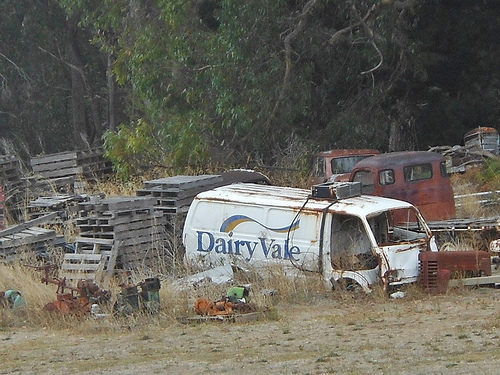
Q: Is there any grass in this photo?
A: Yes, there is grass.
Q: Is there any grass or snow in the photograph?
A: Yes, there is grass.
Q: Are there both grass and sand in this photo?
A: No, there is grass but no sand.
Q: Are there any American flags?
A: No, there are no American flags.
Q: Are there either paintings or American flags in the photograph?
A: No, there are no American flags or paintings.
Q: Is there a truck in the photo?
A: Yes, there is a truck.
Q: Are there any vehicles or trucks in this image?
A: Yes, there is a truck.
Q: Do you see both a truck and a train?
A: No, there is a truck but no trains.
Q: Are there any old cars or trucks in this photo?
A: Yes, there is an old truck.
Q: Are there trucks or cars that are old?
A: Yes, the truck is old.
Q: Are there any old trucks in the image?
A: Yes, there is an old truck.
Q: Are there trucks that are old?
A: Yes, there is a truck that is old.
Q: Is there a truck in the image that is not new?
A: Yes, there is a old truck.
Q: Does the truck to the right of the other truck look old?
A: Yes, the truck is old.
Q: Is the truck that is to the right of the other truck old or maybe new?
A: The truck is old.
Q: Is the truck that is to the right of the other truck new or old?
A: The truck is old.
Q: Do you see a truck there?
A: Yes, there is a truck.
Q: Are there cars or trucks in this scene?
A: Yes, there is a truck.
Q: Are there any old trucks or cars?
A: Yes, there is an old truck.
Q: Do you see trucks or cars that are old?
A: Yes, the truck is old.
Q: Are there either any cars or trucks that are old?
A: Yes, the truck is old.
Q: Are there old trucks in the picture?
A: Yes, there is an old truck.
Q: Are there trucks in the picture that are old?
A: Yes, there is a truck that is old.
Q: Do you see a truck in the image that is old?
A: Yes, there is a truck that is old.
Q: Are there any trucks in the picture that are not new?
A: Yes, there is a old truck.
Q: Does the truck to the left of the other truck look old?
A: Yes, the truck is old.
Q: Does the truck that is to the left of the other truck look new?
A: No, the truck is old.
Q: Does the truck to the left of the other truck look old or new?
A: The truck is old.